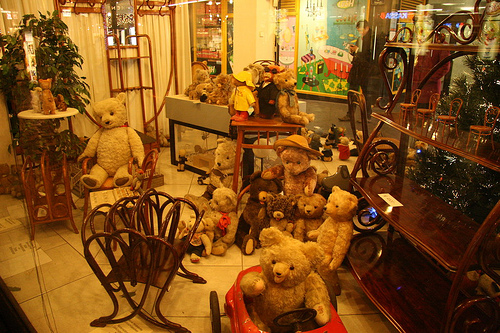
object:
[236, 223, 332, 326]
stuffed bear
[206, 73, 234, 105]
bear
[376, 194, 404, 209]
paper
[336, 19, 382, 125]
man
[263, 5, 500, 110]
store window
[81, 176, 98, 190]
paw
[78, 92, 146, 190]
bear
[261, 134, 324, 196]
bear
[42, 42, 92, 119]
green leaves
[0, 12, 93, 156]
plant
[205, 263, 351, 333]
red car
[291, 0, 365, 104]
painting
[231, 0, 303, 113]
wall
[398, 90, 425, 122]
chairs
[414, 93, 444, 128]
chairs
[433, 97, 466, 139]
chairs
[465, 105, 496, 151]
chairs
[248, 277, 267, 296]
bear paw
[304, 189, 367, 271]
teddy bear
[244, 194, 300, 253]
teddy bear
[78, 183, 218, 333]
rack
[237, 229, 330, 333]
bear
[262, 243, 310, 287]
face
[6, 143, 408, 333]
floor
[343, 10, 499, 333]
shelf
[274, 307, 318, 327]
steering wheel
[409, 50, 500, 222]
christmas tree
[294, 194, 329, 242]
bear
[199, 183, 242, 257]
bear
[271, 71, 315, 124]
bear